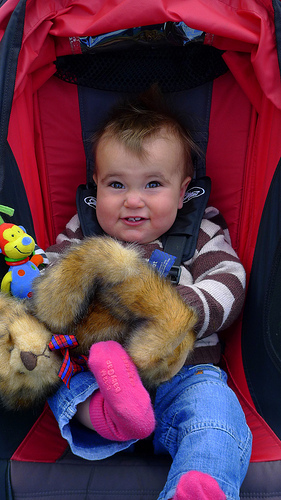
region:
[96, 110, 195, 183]
baby has thin hair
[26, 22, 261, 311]
baby in red pram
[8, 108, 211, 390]
baby holds brown bear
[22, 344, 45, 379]
bear has brown nose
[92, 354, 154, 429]
baby has pink socks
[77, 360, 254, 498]
baby has blue jeans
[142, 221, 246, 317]
red and grey striped shirt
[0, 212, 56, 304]
red yellow and blue bug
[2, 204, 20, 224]
bug toy has green antenna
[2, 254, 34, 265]
green and red rings on bug toy's neck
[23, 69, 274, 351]
baby sitting in stroller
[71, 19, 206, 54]
plastic on stroller cover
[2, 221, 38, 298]
stuffed toy with yellow face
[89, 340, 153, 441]
pink sock on foot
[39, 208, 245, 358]
striped sweater on baby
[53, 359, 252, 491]
blue jeans on legs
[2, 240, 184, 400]
fur on stuffed bear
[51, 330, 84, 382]
plaid ribbon on bear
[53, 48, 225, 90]
black net on stroller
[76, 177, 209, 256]
two black straps on shoulders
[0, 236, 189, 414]
The bear is brown.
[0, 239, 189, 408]
The bear is a toy.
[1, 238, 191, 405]
The bear is stuffed.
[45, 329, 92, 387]
The bear is wearing a ribbon.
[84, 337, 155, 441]
The person is wearing pink socks.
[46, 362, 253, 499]
The person is wearing jeans.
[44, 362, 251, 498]
The jeans are blue.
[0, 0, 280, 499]
The seat is black and red.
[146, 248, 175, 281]
The bear has a tag.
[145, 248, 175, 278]
The tag is blue.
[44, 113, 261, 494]
This is a child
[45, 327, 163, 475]
Leg of a child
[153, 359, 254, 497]
Leg of a child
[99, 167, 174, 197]
Eyes of a child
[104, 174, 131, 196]
Eye of a child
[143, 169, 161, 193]
Eye of a child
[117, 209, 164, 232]
Mouth of a child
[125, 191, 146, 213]
Nose of a child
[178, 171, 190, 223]
Ear of a child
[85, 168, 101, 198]
Ear of a child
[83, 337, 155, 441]
a pink sock on a baby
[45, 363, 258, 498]
jeans on a baby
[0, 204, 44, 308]
a colorful monkey toy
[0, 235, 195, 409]
a brown stuffed bear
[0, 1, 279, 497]
a red and gray baby stroller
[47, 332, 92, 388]
a red and blue ribbon on a stuffed bears neck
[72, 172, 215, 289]
a safety harness holding a baby into a stroller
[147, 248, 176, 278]
a blue tag on a stuffed bear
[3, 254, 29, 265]
green and orange plastic rings on a monkey toy's neck